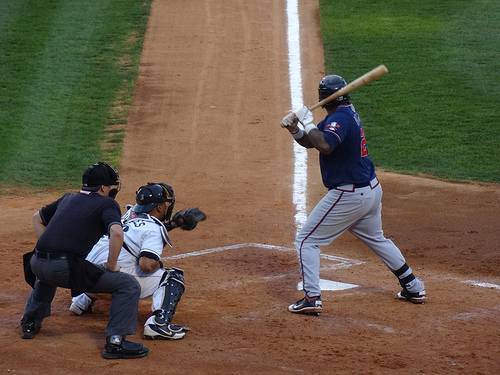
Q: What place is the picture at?
A: It is at the field.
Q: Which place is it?
A: It is a field.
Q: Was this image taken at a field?
A: Yes, it was taken in a field.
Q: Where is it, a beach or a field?
A: It is a field.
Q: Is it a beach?
A: No, it is a field.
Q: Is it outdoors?
A: Yes, it is outdoors.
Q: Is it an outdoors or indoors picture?
A: It is outdoors.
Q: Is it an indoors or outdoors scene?
A: It is outdoors.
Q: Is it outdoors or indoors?
A: It is outdoors.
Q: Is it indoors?
A: No, it is outdoors.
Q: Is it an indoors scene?
A: No, it is outdoors.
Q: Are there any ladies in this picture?
A: No, there are no ladies.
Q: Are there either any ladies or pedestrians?
A: No, there are no ladies or pedestrians.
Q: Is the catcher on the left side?
A: Yes, the catcher is on the left of the image.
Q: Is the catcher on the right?
A: No, the catcher is on the left of the image.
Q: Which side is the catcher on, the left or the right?
A: The catcher is on the left of the image.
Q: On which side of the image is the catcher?
A: The catcher is on the left of the image.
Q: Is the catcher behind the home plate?
A: Yes, the catcher is behind the home plate.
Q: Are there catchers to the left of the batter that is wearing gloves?
A: Yes, there is a catcher to the left of the batter.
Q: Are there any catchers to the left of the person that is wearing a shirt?
A: Yes, there is a catcher to the left of the batter.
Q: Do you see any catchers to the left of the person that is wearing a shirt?
A: Yes, there is a catcher to the left of the batter.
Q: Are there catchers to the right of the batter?
A: No, the catcher is to the left of the batter.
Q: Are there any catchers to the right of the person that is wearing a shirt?
A: No, the catcher is to the left of the batter.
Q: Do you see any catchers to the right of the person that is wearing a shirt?
A: No, the catcher is to the left of the batter.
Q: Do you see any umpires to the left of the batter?
A: No, there is a catcher to the left of the batter.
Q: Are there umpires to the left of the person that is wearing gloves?
A: No, there is a catcher to the left of the batter.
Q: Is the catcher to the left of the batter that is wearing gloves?
A: Yes, the catcher is to the left of the batter.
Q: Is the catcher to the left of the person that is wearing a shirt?
A: Yes, the catcher is to the left of the batter.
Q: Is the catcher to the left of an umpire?
A: No, the catcher is to the left of the batter.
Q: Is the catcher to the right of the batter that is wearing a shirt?
A: No, the catcher is to the left of the batter.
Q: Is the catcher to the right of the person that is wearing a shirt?
A: No, the catcher is to the left of the batter.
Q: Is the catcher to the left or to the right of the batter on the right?
A: The catcher is to the left of the batter.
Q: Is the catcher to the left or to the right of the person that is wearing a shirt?
A: The catcher is to the left of the batter.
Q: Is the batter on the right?
A: Yes, the batter is on the right of the image.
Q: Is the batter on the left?
A: No, the batter is on the right of the image.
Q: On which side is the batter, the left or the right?
A: The batter is on the right of the image.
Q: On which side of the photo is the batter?
A: The batter is on the right of the image.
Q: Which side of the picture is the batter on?
A: The batter is on the right of the image.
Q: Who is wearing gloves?
A: The batter is wearing gloves.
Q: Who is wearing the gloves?
A: The batter is wearing gloves.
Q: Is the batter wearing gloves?
A: Yes, the batter is wearing gloves.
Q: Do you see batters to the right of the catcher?
A: Yes, there is a batter to the right of the catcher.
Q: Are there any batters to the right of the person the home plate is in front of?
A: Yes, there is a batter to the right of the catcher.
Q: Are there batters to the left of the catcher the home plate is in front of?
A: No, the batter is to the right of the catcher.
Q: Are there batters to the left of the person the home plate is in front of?
A: No, the batter is to the right of the catcher.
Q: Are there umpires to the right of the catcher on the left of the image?
A: No, there is a batter to the right of the catcher.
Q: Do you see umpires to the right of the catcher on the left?
A: No, there is a batter to the right of the catcher.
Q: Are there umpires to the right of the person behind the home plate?
A: No, there is a batter to the right of the catcher.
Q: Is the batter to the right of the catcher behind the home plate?
A: Yes, the batter is to the right of the catcher.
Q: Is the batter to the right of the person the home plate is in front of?
A: Yes, the batter is to the right of the catcher.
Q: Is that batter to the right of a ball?
A: No, the batter is to the right of the catcher.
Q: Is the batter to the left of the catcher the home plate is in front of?
A: No, the batter is to the right of the catcher.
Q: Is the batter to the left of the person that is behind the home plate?
A: No, the batter is to the right of the catcher.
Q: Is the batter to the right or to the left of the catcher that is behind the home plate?
A: The batter is to the right of the catcher.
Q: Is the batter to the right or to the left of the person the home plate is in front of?
A: The batter is to the right of the catcher.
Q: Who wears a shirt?
A: The batter wears a shirt.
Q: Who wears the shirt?
A: The batter wears a shirt.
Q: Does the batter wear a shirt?
A: Yes, the batter wears a shirt.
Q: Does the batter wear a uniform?
A: No, the batter wears a shirt.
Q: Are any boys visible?
A: No, there are no boys.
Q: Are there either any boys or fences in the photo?
A: No, there are no boys or fences.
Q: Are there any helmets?
A: Yes, there is a helmet.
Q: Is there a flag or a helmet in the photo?
A: Yes, there is a helmet.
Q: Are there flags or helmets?
A: Yes, there is a helmet.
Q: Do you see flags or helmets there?
A: Yes, there is a helmet.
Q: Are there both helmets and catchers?
A: Yes, there are both a helmet and a catcher.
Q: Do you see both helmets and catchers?
A: Yes, there are both a helmet and a catcher.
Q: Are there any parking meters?
A: No, there are no parking meters.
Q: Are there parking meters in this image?
A: No, there are no parking meters.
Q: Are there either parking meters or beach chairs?
A: No, there are no parking meters or beach chairs.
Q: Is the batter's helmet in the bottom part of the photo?
A: No, the helmet is in the top of the image.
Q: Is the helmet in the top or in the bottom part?
A: The helmet is in the top of the image.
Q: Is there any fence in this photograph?
A: No, there are no fences.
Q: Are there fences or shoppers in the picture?
A: No, there are no fences or shoppers.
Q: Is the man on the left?
A: Yes, the man is on the left of the image.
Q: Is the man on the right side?
A: No, the man is on the left of the image.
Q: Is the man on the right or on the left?
A: The man is on the left of the image.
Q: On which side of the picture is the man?
A: The man is on the left of the image.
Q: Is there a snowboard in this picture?
A: No, there are no snowboards.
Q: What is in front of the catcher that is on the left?
A: The home plate is in front of the catcher.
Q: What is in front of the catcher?
A: The home plate is in front of the catcher.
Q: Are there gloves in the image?
A: Yes, there are gloves.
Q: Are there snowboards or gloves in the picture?
A: Yes, there are gloves.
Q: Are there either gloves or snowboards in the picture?
A: Yes, there are gloves.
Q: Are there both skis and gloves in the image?
A: No, there are gloves but no skis.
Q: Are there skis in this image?
A: No, there are no skis.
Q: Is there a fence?
A: No, there are no fences.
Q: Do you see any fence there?
A: No, there are no fences.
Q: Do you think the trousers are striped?
A: Yes, the trousers are striped.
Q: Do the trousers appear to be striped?
A: Yes, the trousers are striped.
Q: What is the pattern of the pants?
A: The pants are striped.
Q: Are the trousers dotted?
A: No, the trousers are striped.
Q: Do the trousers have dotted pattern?
A: No, the trousers are striped.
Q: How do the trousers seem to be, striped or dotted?
A: The trousers are striped.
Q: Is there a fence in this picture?
A: No, there are no fences.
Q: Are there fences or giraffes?
A: No, there are no fences or giraffes.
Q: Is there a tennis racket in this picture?
A: No, there are no rackets.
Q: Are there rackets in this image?
A: No, there are no rackets.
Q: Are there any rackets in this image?
A: No, there are no rackets.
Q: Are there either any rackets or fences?
A: No, there are no rackets or fences.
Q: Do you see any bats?
A: Yes, there is a bat.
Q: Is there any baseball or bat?
A: Yes, there is a bat.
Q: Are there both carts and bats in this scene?
A: No, there is a bat but no carts.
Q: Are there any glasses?
A: No, there are no glasses.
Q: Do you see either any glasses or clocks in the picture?
A: No, there are no glasses or clocks.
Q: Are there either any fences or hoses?
A: No, there are no fences or hoses.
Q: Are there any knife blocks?
A: No, there are no knife blocks.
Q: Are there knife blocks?
A: No, there are no knife blocks.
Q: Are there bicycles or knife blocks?
A: No, there are no knife blocks or bicycles.